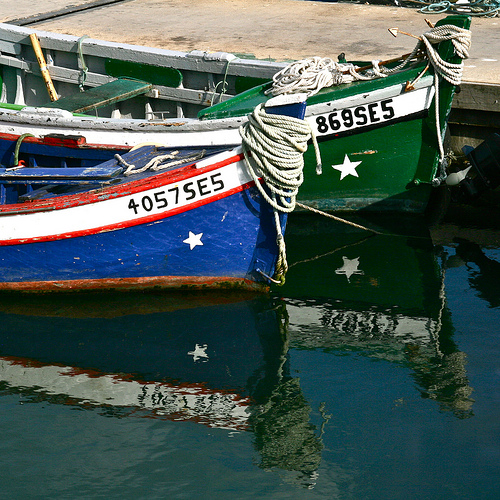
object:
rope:
[238, 102, 323, 213]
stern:
[233, 100, 307, 294]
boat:
[0, 101, 305, 291]